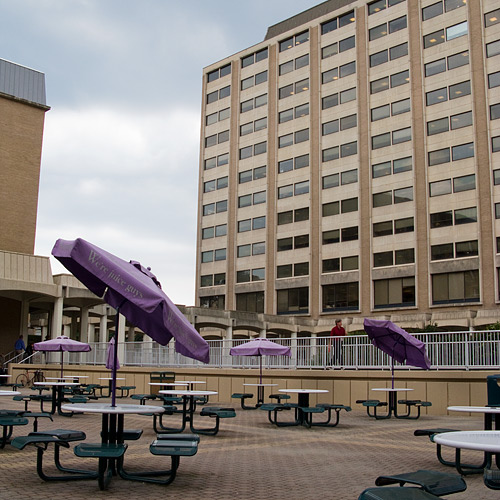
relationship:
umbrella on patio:
[49, 213, 258, 363] [111, 337, 498, 455]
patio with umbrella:
[111, 337, 498, 455] [49, 213, 258, 363]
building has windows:
[208, 83, 490, 296] [258, 99, 447, 178]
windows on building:
[258, 99, 447, 178] [208, 83, 490, 296]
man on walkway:
[317, 283, 376, 386] [241, 300, 492, 387]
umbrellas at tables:
[64, 256, 437, 403] [60, 370, 408, 490]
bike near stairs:
[18, 360, 69, 396] [6, 331, 119, 419]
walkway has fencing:
[241, 300, 492, 387] [45, 329, 499, 370]